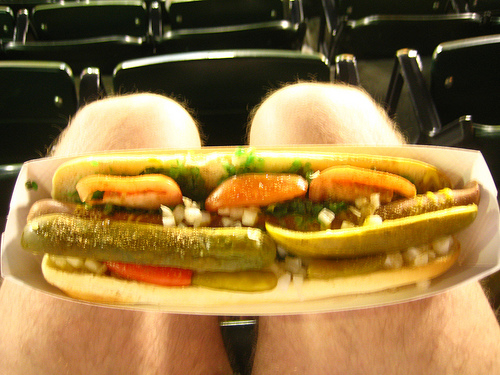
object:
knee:
[49, 92, 201, 155]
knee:
[248, 81, 404, 146]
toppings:
[19, 165, 480, 292]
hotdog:
[26, 182, 481, 231]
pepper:
[195, 271, 278, 291]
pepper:
[305, 253, 387, 276]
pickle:
[21, 214, 275, 272]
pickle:
[266, 205, 479, 258]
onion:
[186, 208, 200, 221]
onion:
[318, 206, 333, 225]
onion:
[367, 215, 383, 226]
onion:
[435, 237, 452, 254]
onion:
[159, 202, 173, 215]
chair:
[83, 50, 362, 148]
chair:
[385, 36, 500, 146]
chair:
[0, 59, 108, 165]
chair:
[319, 10, 484, 60]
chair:
[152, 4, 307, 48]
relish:
[139, 166, 208, 205]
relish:
[274, 197, 349, 229]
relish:
[220, 147, 268, 174]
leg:
[0, 276, 231, 373]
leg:
[250, 279, 499, 373]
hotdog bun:
[41, 152, 462, 308]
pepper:
[106, 259, 194, 288]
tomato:
[76, 173, 182, 213]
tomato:
[207, 172, 307, 210]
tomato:
[305, 166, 417, 202]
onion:
[386, 253, 404, 269]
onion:
[230, 209, 246, 219]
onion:
[368, 191, 379, 208]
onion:
[412, 253, 426, 264]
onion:
[283, 255, 300, 271]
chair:
[5, 15, 148, 61]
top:
[448, 115, 500, 141]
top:
[328, 12, 482, 41]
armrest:
[395, 48, 440, 135]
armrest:
[334, 54, 360, 87]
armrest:
[78, 67, 103, 104]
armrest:
[150, 3, 162, 36]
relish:
[25, 181, 37, 191]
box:
[2, 144, 499, 318]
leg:
[384, 66, 403, 121]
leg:
[315, 12, 328, 53]